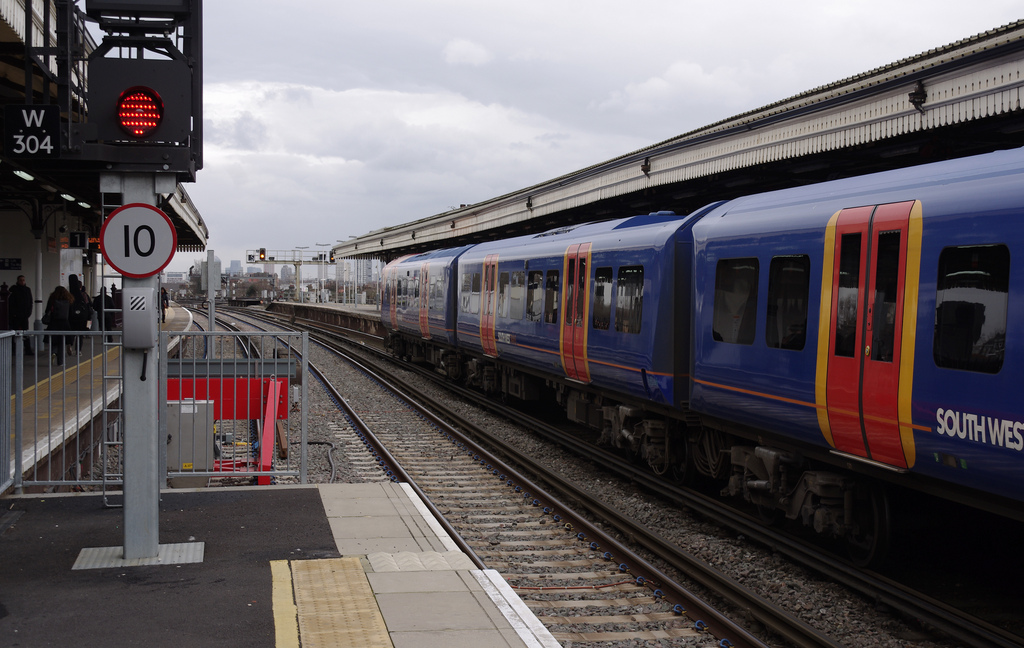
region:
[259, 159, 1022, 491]
blue red and yellow train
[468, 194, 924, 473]
red train doors with yellow trim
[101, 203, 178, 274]
white circle with red rim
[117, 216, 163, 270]
black numbers on white sign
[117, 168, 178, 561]
gray post white sign is on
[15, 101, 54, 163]
white lettering on dark gray background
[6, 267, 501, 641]
platform next to the train tracks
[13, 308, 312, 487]
gray railing on the platform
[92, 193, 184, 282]
Round white sign with the number 10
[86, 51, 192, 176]
Black sign with red light on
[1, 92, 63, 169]
Sign reading W 304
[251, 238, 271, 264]
Sign with yellow light on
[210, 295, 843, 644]
Empty metal train track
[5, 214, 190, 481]
Group of people standing on platfrom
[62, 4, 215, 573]
Silver metal sign with black box at top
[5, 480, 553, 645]
Black platform with gray tile edge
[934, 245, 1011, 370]
glass window on the blue train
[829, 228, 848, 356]
glass window on the blue train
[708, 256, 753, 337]
glass window on the blue train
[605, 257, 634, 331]
glass window on the blue train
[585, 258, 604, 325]
glass window on the blue train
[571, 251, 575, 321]
glass window on the blue train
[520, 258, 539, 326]
glass window on the blue train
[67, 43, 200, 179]
signal light is red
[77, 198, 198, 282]
red and white sign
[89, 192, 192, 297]
red and white sign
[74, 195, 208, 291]
red and white sign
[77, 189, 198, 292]
red and white sign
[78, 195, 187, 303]
red and white sign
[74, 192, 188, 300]
red and white sign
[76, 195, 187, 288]
red and white sign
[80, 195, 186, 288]
red and white sign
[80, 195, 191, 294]
red and white sign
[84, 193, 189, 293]
red and white sign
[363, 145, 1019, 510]
train on the tracks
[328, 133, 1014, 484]
the train is blue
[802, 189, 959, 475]
yellow trim around doors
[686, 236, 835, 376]
a pair of windows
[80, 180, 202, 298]
a white and black sign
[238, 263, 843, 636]
a set of tracks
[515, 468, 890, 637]
gravel on the tracks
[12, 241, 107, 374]
people in the distance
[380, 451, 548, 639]
white trim on platform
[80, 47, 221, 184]
red lit railroad sign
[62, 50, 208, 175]
red lit railroad sign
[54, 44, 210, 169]
red lit railroad sign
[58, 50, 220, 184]
red lit railroad light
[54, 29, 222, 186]
red lit railroad light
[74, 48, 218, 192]
red lit railroad light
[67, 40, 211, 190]
red lit railroad light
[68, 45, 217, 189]
red lit railroad light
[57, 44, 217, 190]
red lit railroad light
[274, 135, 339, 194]
white clouds in blue sky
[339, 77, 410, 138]
white clouds in blue sky